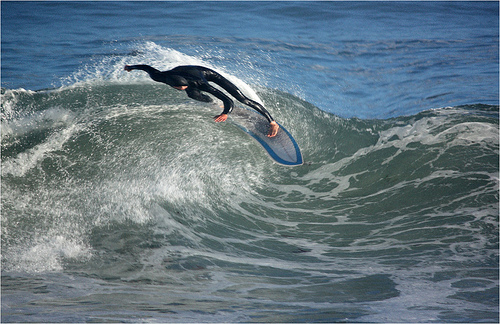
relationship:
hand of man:
[216, 112, 229, 122] [122, 63, 278, 138]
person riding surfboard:
[112, 56, 279, 141] [221, 110, 305, 167]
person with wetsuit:
[123, 64, 279, 138] [162, 55, 239, 116]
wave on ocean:
[9, 33, 486, 256] [3, 0, 498, 323]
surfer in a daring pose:
[117, 60, 280, 140] [164, 50, 314, 189]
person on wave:
[123, 64, 279, 138] [41, 49, 431, 181]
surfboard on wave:
[219, 103, 303, 165] [42, 82, 214, 196]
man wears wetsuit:
[124, 64, 280, 138] [126, 59, 278, 131]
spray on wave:
[137, 30, 175, 60] [2, 70, 497, 322]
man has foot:
[124, 64, 280, 138] [260, 116, 282, 143]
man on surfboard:
[120, 55, 280, 137] [232, 95, 304, 166]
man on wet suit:
[120, 55, 280, 137] [132, 58, 271, 116]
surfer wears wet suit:
[124, 65, 279, 138] [123, 58, 283, 143]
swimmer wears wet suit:
[118, 59, 283, 153] [128, 61, 270, 118]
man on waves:
[124, 64, 280, 138] [76, 73, 360, 261]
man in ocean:
[124, 64, 280, 138] [3, 0, 498, 323]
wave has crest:
[6, 46, 256, 144] [6, 66, 138, 101]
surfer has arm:
[124, 65, 279, 138] [121, 63, 158, 81]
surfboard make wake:
[219, 103, 303, 165] [238, 81, 278, 110]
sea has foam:
[3, 2, 498, 322] [2, 80, 499, 322]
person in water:
[123, 64, 279, 138] [2, 43, 497, 319]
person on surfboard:
[112, 56, 279, 141] [239, 107, 306, 167]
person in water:
[112, 56, 279, 141] [3, 2, 498, 321]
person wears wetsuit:
[123, 64, 279, 138] [127, 65, 272, 122]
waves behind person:
[92, 63, 249, 223] [149, 51, 335, 189]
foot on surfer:
[265, 111, 280, 141] [111, 50, 283, 150]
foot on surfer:
[209, 110, 229, 123] [111, 50, 283, 150]